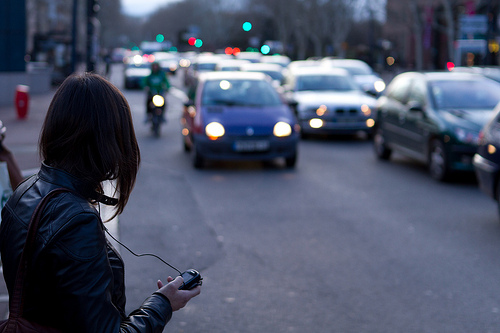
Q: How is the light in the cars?
A: On.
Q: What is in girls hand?
A: Cell phone.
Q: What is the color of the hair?
A: Black.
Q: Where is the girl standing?
A: In the sidewalk.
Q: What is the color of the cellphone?
A: Black.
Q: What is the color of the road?
A: Grey.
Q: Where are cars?
A: On the street.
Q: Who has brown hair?
A: A woman.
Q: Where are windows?
A: On cars.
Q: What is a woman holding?
A: Cell phone.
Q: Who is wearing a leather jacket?
A: The woman.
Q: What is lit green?
A: Traffic lights.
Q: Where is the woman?
A: On the sidewalk.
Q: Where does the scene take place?
A: On a city street.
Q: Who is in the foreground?
A: A woman in a leather jacket.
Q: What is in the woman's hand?
A: A phone.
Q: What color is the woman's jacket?
A: Black.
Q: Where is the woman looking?
A: Towards the cars.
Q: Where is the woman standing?
A: By the road.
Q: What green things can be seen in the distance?
A: Traffic lights.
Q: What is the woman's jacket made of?
A: Leather.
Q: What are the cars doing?
A: Moving.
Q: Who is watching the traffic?
A: A woman with dark hair.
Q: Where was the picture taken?
A: On a city street.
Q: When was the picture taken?
A: At dusk.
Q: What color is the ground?
A: Dark grey.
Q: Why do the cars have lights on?
A: It's the evening.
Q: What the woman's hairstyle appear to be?
A: A bob.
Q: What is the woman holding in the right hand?
A: A cell phone.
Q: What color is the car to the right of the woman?
A: Blue.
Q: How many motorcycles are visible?
A: One.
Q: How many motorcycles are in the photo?
A: One.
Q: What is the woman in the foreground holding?
A: Cell phone.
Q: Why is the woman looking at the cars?
A: Waiting to cross the road.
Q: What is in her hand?
A: A cell phone.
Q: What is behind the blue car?
A: A motorcycle.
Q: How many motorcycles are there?
A: One.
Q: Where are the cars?
A: On the road.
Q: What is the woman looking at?
A: The cars.